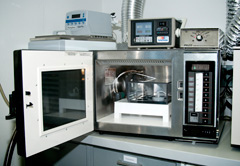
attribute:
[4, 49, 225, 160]
oven — open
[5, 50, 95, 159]
door — white, open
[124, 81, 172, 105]
container — metallic, shiny, metal, glass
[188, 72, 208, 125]
buttons — black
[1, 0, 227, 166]
wall — white, grey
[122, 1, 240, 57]
tubing — metallic, silver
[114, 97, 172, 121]
microwave table — white, small, solid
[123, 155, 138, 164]
label — white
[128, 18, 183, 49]
monitoring device — electronic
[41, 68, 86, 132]
window — glass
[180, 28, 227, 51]
monitor — beige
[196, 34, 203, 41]
dial — black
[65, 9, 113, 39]
electronic device — blue, grey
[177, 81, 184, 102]
slots — small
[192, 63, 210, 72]
display — digital